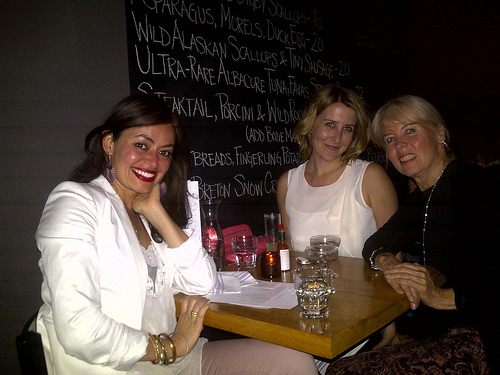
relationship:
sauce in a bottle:
[273, 222, 295, 272] [280, 232, 291, 265]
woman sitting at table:
[28, 92, 317, 375] [353, 273, 375, 302]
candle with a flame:
[260, 245, 279, 275] [261, 251, 275, 263]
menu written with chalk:
[130, 0, 331, 202] [200, 68, 238, 82]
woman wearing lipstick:
[28, 92, 315, 374] [133, 164, 155, 182]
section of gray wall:
[3, 3, 73, 142] [1, 0, 125, 141]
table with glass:
[174, 247, 447, 359] [296, 276, 333, 316]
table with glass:
[174, 247, 447, 359] [263, 212, 284, 250]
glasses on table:
[288, 235, 345, 317] [187, 219, 431, 366]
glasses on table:
[230, 233, 260, 268] [174, 247, 447, 359]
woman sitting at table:
[35, 75, 497, 366] [342, 287, 392, 309]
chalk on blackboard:
[130, 0, 385, 200] [125, 0, 407, 207]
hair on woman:
[371, 95, 446, 149] [361, 90, 493, 373]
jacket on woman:
[76, 215, 146, 355] [35, 73, 223, 373]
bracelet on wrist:
[167, 328, 191, 365] [380, 260, 390, 270]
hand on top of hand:
[382, 252, 440, 305] [388, 281, 418, 310]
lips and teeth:
[131, 162, 159, 186] [130, 164, 159, 182]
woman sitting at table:
[28, 92, 317, 375] [200, 255, 427, 373]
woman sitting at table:
[271, 82, 397, 259] [200, 255, 427, 373]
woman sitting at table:
[315, 90, 498, 375] [200, 255, 427, 373]